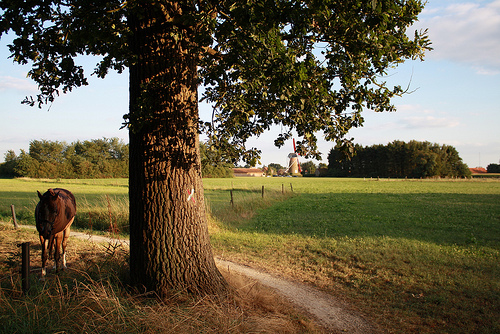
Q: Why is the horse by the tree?
A: For shade.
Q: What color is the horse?
A: Brown.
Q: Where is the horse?
A: By the tree.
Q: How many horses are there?
A: 1.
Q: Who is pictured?
A: The horse.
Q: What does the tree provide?
A: Shade.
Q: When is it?
A: Day time.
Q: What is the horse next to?
A: A tree.